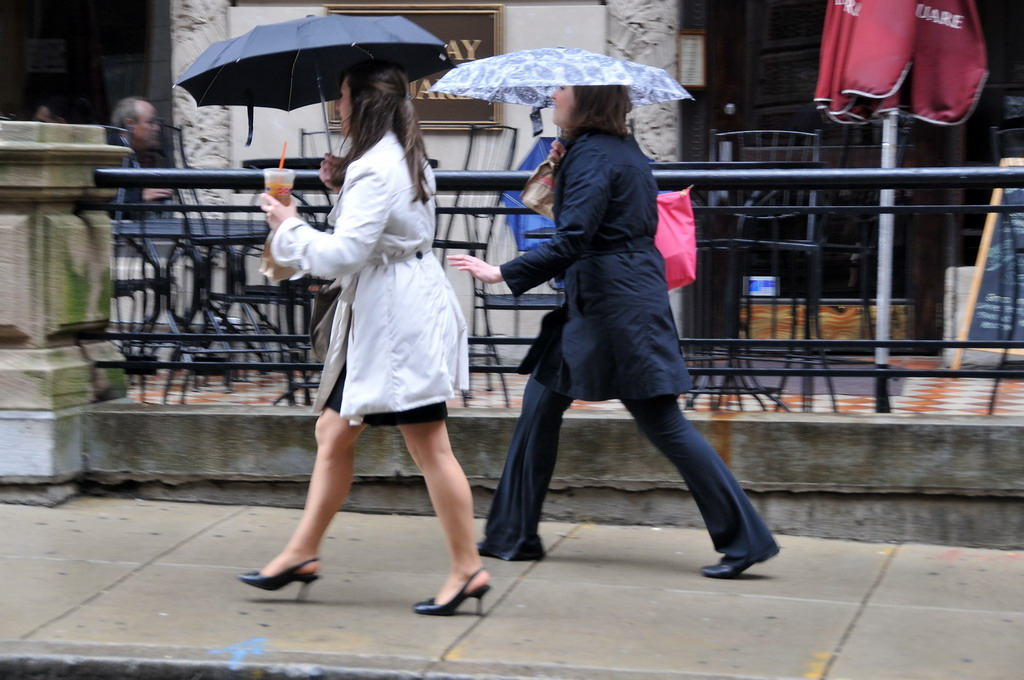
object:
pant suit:
[485, 377, 784, 564]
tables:
[113, 127, 400, 230]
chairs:
[177, 188, 329, 411]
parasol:
[817, 0, 999, 374]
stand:
[857, 123, 926, 419]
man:
[89, 95, 182, 238]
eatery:
[39, 12, 1022, 419]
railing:
[95, 153, 1013, 212]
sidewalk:
[49, 360, 1013, 667]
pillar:
[0, 117, 133, 511]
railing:
[39, 136, 1020, 257]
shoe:
[237, 552, 325, 603]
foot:
[234, 557, 326, 603]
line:
[807, 617, 846, 672]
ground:
[8, 445, 1023, 661]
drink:
[261, 140, 299, 217]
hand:
[259, 190, 299, 228]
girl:
[234, 67, 494, 618]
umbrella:
[159, 4, 463, 109]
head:
[334, 64, 416, 146]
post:
[89, 152, 329, 195]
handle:
[314, 165, 355, 189]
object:
[170, 17, 457, 115]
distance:
[30, 32, 930, 368]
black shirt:
[324, 358, 450, 427]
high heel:
[288, 576, 321, 603]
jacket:
[503, 115, 693, 405]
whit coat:
[265, 115, 482, 424]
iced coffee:
[261, 177, 292, 210]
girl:
[445, 70, 780, 580]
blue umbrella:
[413, 47, 698, 102]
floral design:
[469, 51, 615, 77]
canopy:
[429, 44, 683, 109]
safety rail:
[120, 171, 171, 405]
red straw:
[276, 140, 291, 172]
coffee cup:
[263, 167, 302, 219]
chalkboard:
[946, 157, 1024, 383]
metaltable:
[673, 152, 868, 416]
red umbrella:
[806, 0, 992, 372]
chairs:
[643, 113, 830, 414]